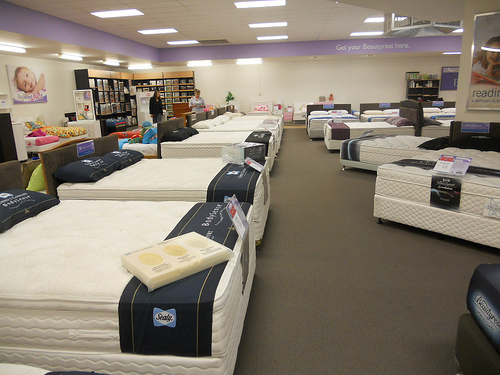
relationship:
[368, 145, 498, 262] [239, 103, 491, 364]
mattress in room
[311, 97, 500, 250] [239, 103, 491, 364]
mattress in room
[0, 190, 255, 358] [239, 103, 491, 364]
mattress in room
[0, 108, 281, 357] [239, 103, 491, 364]
mattress in room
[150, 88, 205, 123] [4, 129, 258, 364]
people looking at mattresses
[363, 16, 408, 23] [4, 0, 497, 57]
light on ceiling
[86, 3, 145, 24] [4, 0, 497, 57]
light on ceiling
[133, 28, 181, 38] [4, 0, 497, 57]
light on ceiling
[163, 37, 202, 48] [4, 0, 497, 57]
light on ceiling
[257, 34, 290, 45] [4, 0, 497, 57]
light on ceiling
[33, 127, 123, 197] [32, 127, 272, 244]
headboard for a bed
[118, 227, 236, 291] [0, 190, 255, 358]
object on mattress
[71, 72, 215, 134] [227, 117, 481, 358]
case on floor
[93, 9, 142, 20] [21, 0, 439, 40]
light on ceiling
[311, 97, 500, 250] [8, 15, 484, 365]
mattress in store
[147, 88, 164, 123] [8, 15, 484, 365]
people in store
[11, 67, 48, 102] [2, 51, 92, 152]
baby on wall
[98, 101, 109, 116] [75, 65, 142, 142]
item on shelf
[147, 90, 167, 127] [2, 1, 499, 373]
person in showroom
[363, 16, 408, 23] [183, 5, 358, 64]
light in ceiling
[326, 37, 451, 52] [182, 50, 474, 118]
border on wall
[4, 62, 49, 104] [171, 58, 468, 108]
picture on wall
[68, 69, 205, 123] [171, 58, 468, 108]
display against wall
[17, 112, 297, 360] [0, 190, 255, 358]
sheets attached to mattress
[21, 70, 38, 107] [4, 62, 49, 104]
face in picture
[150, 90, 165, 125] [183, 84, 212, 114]
person and customer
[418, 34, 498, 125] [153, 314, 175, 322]
poster with words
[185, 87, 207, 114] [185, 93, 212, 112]
woman wearing shirt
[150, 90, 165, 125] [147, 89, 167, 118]
person wearing dark shirt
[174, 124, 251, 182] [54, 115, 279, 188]
pillows on bed